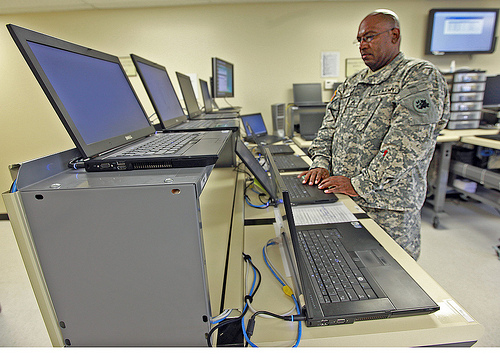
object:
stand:
[0, 161, 485, 350]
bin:
[434, 68, 488, 131]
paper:
[288, 202, 359, 226]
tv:
[425, 7, 499, 58]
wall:
[1, 0, 499, 214]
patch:
[398, 80, 440, 126]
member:
[291, 9, 448, 259]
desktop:
[210, 57, 243, 112]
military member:
[292, 9, 449, 220]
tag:
[368, 85, 400, 96]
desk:
[242, 160, 370, 222]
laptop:
[4, 23, 242, 173]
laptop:
[130, 53, 241, 131]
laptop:
[174, 71, 238, 120]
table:
[433, 122, 500, 150]